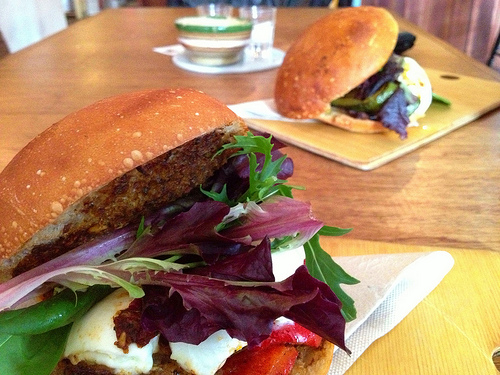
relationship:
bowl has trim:
[174, 16, 251, 68] [174, 15, 253, 34]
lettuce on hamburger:
[2, 277, 115, 373] [0, 87, 342, 371]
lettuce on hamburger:
[115, 199, 347, 351] [0, 87, 342, 371]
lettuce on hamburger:
[341, 31, 419, 137] [275, 5, 433, 138]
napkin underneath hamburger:
[219, 96, 317, 122] [275, 5, 433, 138]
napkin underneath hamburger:
[317, 251, 456, 374] [0, 87, 342, 371]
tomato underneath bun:
[242, 315, 324, 350] [0, 86, 253, 282]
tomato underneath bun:
[230, 346, 298, 374] [0, 86, 253, 282]